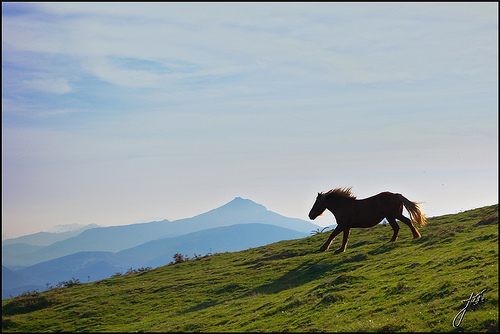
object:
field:
[4, 197, 495, 333]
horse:
[307, 184, 422, 254]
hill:
[3, 198, 497, 333]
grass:
[6, 197, 499, 334]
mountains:
[1, 195, 297, 241]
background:
[10, 75, 496, 260]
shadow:
[170, 247, 363, 314]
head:
[305, 192, 326, 221]